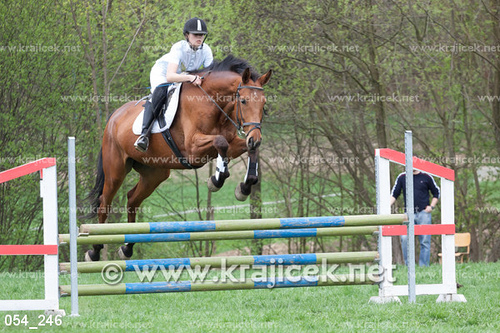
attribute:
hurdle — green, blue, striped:
[66, 209, 416, 318]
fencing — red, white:
[10, 129, 470, 319]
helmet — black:
[182, 17, 209, 37]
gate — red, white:
[371, 142, 471, 303]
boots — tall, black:
[134, 103, 154, 153]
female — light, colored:
[132, 8, 237, 146]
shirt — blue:
[392, 159, 435, 212]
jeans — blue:
[404, 209, 430, 272]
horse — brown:
[81, 54, 273, 262]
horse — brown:
[87, 61, 293, 223]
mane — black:
[188, 50, 274, 89]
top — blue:
[392, 168, 442, 214]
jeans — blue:
[399, 208, 435, 270]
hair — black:
[92, 57, 284, 191]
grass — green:
[2, 270, 498, 329]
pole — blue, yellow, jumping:
[72, 215, 424, 233]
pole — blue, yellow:
[52, 268, 385, 296]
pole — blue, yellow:
[55, 250, 389, 270]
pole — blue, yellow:
[56, 217, 385, 244]